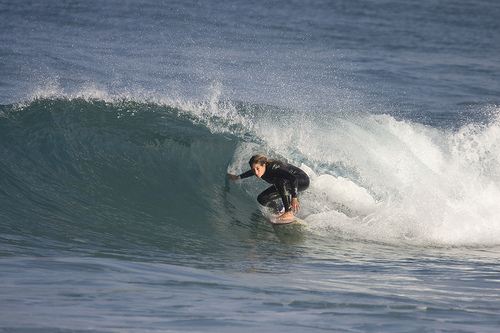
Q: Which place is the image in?
A: It is at the ocean.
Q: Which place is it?
A: It is an ocean.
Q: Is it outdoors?
A: Yes, it is outdoors.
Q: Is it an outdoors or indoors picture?
A: It is outdoors.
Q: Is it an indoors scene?
A: No, it is outdoors.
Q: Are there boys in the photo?
A: No, there are no boys.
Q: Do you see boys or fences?
A: No, there are no boys or fences.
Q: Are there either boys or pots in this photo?
A: No, there are no boys or pots.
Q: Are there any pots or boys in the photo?
A: No, there are no boys or pots.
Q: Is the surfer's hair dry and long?
A: No, the hair is long but wet.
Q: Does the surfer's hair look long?
A: Yes, the hair is long.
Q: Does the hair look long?
A: Yes, the hair is long.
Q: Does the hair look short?
A: No, the hair is long.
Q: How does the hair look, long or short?
A: The hair is long.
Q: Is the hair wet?
A: Yes, the hair is wet.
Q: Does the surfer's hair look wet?
A: Yes, the hair is wet.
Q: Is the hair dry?
A: No, the hair is wet.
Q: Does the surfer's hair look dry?
A: No, the hair is wet.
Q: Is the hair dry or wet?
A: The hair is wet.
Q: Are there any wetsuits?
A: Yes, there is a wetsuit.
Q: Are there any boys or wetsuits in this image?
A: Yes, there is a wetsuit.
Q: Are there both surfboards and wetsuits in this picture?
A: Yes, there are both a wetsuit and a surfboard.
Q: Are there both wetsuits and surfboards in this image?
A: Yes, there are both a wetsuit and a surfboard.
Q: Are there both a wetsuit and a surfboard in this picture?
A: Yes, there are both a wetsuit and a surfboard.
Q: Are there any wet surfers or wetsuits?
A: Yes, there is a wet wetsuit.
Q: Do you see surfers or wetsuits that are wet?
A: Yes, the wetsuit is wet.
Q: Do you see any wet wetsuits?
A: Yes, there is a wet wetsuit.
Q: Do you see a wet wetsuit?
A: Yes, there is a wet wetsuit.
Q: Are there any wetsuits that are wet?
A: Yes, there is a wetsuit that is wet.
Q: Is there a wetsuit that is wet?
A: Yes, there is a wetsuit that is wet.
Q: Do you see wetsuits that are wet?
A: Yes, there is a wetsuit that is wet.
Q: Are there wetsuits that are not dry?
A: Yes, there is a wet wetsuit.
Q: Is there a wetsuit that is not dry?
A: Yes, there is a wet wetsuit.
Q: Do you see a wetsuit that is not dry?
A: Yes, there is a wet wetsuit.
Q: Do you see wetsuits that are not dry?
A: Yes, there is a wet wetsuit.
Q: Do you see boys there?
A: No, there are no boys.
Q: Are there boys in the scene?
A: No, there are no boys.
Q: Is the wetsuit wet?
A: Yes, the wetsuit is wet.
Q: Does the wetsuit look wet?
A: Yes, the wetsuit is wet.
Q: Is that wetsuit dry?
A: No, the wetsuit is wet.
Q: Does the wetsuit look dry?
A: No, the wetsuit is wet.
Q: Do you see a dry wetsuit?
A: No, there is a wetsuit but it is wet.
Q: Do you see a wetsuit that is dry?
A: No, there is a wetsuit but it is wet.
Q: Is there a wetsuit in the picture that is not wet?
A: No, there is a wetsuit but it is wet.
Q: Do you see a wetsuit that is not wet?
A: No, there is a wetsuit but it is wet.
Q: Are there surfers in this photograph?
A: Yes, there is a surfer.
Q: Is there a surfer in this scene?
A: Yes, there is a surfer.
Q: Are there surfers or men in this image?
A: Yes, there is a surfer.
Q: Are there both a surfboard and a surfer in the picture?
A: Yes, there are both a surfer and a surfboard.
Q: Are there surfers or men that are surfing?
A: Yes, the surfer is surfing.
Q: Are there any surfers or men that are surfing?
A: Yes, the surfer is surfing.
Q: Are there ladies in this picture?
A: No, there are no ladies.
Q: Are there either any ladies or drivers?
A: No, there are no ladies or drivers.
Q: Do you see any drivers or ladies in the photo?
A: No, there are no ladies or drivers.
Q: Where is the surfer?
A: The surfer is in the ocean.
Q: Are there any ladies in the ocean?
A: No, there is a surfer in the ocean.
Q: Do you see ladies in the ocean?
A: No, there is a surfer in the ocean.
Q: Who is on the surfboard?
A: The surfer is on the surfboard.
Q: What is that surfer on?
A: The surfer is on the surfboard.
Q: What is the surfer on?
A: The surfer is on the surfboard.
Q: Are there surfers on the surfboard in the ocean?
A: Yes, there is a surfer on the surfboard.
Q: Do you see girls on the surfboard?
A: No, there is a surfer on the surfboard.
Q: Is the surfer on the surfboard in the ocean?
A: Yes, the surfer is on the surfboard.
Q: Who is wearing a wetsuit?
A: The surfer is wearing a wetsuit.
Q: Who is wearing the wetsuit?
A: The surfer is wearing a wetsuit.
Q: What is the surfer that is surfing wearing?
A: The surfer is wearing a wetsuit.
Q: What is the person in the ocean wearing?
A: The surfer is wearing a wetsuit.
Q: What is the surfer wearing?
A: The surfer is wearing a wetsuit.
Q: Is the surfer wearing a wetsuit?
A: Yes, the surfer is wearing a wetsuit.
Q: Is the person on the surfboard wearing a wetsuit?
A: Yes, the surfer is wearing a wetsuit.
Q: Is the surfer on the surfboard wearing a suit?
A: No, the surfer is wearing a wetsuit.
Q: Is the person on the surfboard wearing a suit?
A: No, the surfer is wearing a wetsuit.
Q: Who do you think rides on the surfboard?
A: The surfer rides on the surfboard.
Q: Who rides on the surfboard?
A: The surfer rides on the surfboard.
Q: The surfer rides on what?
A: The surfer rides on the surfboard.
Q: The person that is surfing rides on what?
A: The surfer rides on the surfboard.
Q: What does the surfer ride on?
A: The surfer rides on the surfboard.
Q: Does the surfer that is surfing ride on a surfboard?
A: Yes, the surfer rides on a surfboard.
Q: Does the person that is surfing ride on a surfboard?
A: Yes, the surfer rides on a surfboard.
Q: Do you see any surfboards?
A: Yes, there is a surfboard.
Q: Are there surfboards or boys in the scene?
A: Yes, there is a surfboard.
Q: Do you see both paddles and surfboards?
A: No, there is a surfboard but no paddles.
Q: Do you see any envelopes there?
A: No, there are no envelopes.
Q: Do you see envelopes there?
A: No, there are no envelopes.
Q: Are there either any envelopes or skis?
A: No, there are no envelopes or skis.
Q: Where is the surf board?
A: The surf board is in the ocean.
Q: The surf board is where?
A: The surf board is in the ocean.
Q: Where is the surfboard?
A: The surf board is in the ocean.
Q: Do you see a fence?
A: No, there are no fences.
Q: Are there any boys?
A: No, there are no boys.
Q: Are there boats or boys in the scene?
A: No, there are no boys or boats.